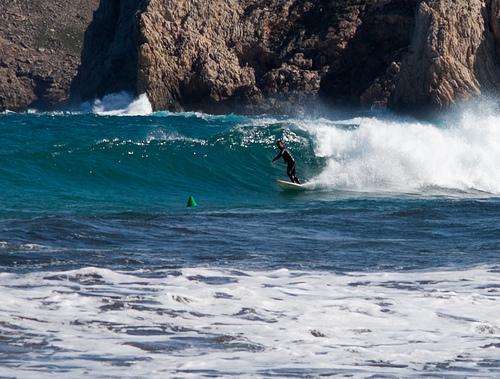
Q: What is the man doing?
A: Surfing.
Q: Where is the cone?
A: In the water.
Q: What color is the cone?
A: Green.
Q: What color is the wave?
A: White.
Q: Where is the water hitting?
A: The rocks.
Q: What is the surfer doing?
A: Riding the wave.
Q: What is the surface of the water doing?
A: Foaming.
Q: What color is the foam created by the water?
A: White.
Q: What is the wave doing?
A: Crashing.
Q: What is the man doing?
A: Surfing.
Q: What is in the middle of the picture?
A: A green cone.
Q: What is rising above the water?
A: A large cliff.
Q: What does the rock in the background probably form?
A: Cliffs.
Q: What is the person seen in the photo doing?
A: Surfing.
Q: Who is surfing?
A: A man.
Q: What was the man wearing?
A: A wetsuit.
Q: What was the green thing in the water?
A: A cone.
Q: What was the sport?
A: Surfing.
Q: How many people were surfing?
A: One.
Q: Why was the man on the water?
A: He was surfing.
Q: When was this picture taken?
A: During the day.